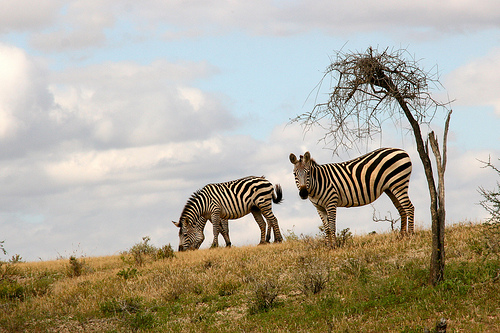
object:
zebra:
[286, 147, 417, 247]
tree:
[309, 43, 461, 294]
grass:
[0, 223, 499, 333]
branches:
[337, 60, 382, 85]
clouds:
[0, 0, 499, 264]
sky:
[0, 0, 499, 257]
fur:
[188, 197, 198, 209]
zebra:
[169, 174, 284, 253]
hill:
[0, 222, 499, 332]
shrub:
[213, 285, 234, 298]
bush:
[471, 158, 499, 240]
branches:
[484, 217, 500, 231]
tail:
[269, 183, 285, 204]